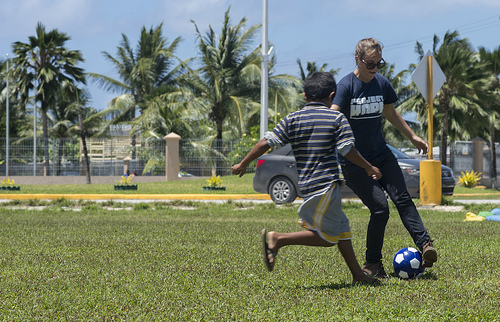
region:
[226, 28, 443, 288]
Man and boy playing soccer.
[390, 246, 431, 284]
Blue and white soccer ball.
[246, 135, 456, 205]
Gray car parked in parking lot.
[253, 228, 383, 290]
Young boy wearing sandals on feet.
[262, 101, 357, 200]
Young boy dressed in striped shirt.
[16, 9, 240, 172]
Palm trees growing in background.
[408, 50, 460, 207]
Yellow post holding traffic sign.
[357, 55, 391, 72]
Man wearing sunglasses over eyes.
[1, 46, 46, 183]
Lamp post in background of soccer field.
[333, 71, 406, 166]
Man dressed in navy blue t-shirt with white writing on front.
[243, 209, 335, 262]
Boy has right foot in air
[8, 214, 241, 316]
Grass is green and cut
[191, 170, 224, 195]
Yellow flowers in pot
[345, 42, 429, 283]
Woman is kicking soccer ball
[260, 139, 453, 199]
Silver car parked by curb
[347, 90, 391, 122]
Woman's shirt has writing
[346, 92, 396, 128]
Writing on shirt is white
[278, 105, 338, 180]
Boy has a striped shirt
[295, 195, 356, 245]
Boy has yellow trim on shorts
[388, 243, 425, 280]
Ball is blue and white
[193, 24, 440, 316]
two people playing soccer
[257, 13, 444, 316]
an adult and child playing soccer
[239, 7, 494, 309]
an adult kicking the soccer ball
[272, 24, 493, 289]
an adult kicking the blue soccer ball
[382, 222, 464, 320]
a blue and white soccer ball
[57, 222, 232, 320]
a green grass field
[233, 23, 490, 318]
two people kicking a ball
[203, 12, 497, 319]
two people running around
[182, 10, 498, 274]
two people running after a ball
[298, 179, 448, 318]
a blue ball rolling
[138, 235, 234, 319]
the grass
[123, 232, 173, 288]
the grass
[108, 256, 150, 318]
the grass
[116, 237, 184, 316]
the grass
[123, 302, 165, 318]
the grass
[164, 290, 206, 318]
the grass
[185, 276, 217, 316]
the grass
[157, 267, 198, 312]
the grass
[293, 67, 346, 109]
the head of a boy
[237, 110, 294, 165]
the arm of a boy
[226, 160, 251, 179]
the hand of a boy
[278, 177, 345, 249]
the leg of a boy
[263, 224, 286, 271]
the foot of a boy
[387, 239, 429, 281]
a blue and white soccer ball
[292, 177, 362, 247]
a pair of shorts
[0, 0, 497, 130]
a clear blue sky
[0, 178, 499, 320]
a green grassy field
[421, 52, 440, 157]
a yellow sign post